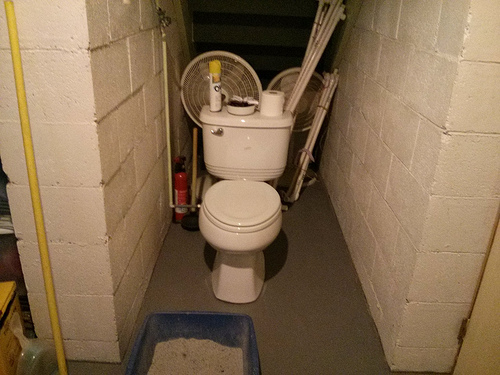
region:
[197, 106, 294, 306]
a toilet bowl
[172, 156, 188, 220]
a red fire extinguisher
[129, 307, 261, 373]
a blue litter box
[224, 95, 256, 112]
an ashtray on a toilet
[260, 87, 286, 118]
a roll of white toilet paper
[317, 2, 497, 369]
a white cinder block wall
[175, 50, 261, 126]
a white tall fan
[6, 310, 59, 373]
a transparent dust pan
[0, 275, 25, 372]
a yellow box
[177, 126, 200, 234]
a black plunger with a wooden handle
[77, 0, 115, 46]
a square white tile on a wall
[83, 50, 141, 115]
a square white tile on a wall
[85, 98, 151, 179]
a square white tile on a wall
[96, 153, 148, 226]
a square white tile on a wall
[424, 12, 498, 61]
a square white tile on a wall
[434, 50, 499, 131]
a square white tile on a wall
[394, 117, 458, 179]
a square white tile on a wall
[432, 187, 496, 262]
a square white tile on a wall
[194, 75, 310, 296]
a white toilet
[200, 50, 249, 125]
a can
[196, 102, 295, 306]
A white toilet.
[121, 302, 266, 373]
A blue bin.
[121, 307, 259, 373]
A litter box for a cat.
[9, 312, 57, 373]
A clear dust pan.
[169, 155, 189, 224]
A red fire extinguisher.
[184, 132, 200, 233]
A toilet plunger.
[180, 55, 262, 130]
A round white fan.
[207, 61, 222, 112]
A can of air freshener with a yellow lid.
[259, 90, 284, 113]
A white roll of toilet paper.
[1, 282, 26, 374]
A yellow box.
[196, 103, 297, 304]
a toilet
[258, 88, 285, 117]
a roll of toilet paper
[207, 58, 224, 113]
a spray can of air freshener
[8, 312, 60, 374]
a dustpan in the corner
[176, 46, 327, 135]
two fans behind the toilet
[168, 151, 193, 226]
a fire extinguisher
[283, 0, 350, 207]
bundles of flourescent lightbulbs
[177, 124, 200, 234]
a toilet plunger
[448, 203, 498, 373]
the corner of a door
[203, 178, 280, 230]
The lid of the toilet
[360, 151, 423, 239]
The walls are white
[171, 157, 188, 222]
A fire extinguisher near the toilet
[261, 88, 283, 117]
Toilet paper on the toilet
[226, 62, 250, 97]
A fan behind the toilet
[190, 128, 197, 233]
The plunger behind the toilet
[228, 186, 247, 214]
The toilet is white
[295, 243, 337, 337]
The ground is gray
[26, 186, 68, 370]
A yellow pole near the wall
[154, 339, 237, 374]
Kitty littler in the blue box